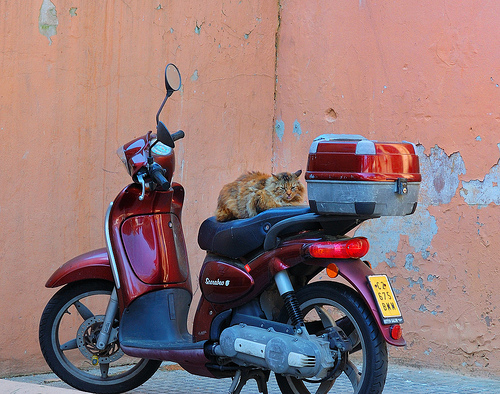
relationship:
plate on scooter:
[367, 274, 403, 326] [23, 116, 458, 389]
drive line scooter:
[213, 316, 348, 370] [23, 116, 458, 389]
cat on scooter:
[218, 165, 301, 223] [23, 116, 458, 389]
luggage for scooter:
[307, 132, 423, 214] [23, 116, 458, 389]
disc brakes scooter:
[73, 313, 126, 367] [23, 116, 458, 389]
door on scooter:
[307, 132, 423, 214] [23, 116, 458, 389]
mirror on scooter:
[161, 66, 188, 90] [23, 116, 458, 389]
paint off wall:
[375, 146, 499, 277] [2, 0, 495, 373]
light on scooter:
[309, 237, 370, 259] [23, 116, 458, 389]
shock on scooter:
[106, 291, 120, 356] [23, 116, 458, 389]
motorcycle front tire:
[23, 116, 458, 389] [36, 275, 174, 388]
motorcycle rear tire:
[23, 116, 458, 389] [265, 283, 379, 379]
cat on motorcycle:
[218, 165, 301, 223] [23, 116, 458, 389]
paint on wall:
[375, 146, 499, 277] [2, 0, 495, 373]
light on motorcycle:
[309, 237, 370, 259] [23, 116, 458, 389]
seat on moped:
[202, 210, 311, 259] [23, 116, 458, 389]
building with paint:
[2, 0, 495, 373] [375, 146, 499, 277]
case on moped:
[307, 132, 423, 214] [23, 116, 458, 389]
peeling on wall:
[375, 146, 499, 277] [2, 0, 495, 373]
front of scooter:
[36, 275, 174, 388] [23, 116, 458, 389]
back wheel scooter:
[265, 283, 379, 379] [23, 116, 458, 389]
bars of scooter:
[129, 123, 183, 206] [23, 116, 458, 389]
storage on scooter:
[307, 132, 423, 214] [23, 116, 458, 389]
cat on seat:
[218, 165, 301, 223] [202, 210, 311, 259]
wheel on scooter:
[36, 275, 174, 388] [23, 116, 458, 389]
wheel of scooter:
[36, 275, 174, 388] [23, 116, 458, 389]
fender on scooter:
[50, 241, 116, 295] [23, 116, 458, 389]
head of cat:
[268, 168, 305, 200] [218, 165, 301, 223]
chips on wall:
[424, 140, 495, 246] [2, 0, 495, 373]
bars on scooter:
[129, 123, 183, 206] [23, 116, 458, 389]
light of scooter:
[300, 221, 384, 270] [17, 60, 418, 391]